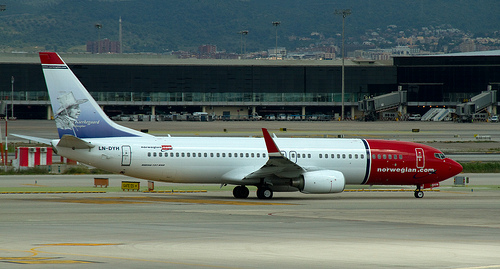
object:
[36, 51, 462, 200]
plane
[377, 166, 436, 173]
logo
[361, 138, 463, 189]
front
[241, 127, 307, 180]
wing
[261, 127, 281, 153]
tip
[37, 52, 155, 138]
tip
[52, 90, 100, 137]
portrait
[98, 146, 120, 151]
letters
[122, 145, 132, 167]
door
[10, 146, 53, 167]
barrier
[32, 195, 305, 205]
lines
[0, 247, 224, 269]
lines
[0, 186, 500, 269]
concrete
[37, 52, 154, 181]
terminal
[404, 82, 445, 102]
gates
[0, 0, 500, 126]
background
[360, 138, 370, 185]
stripe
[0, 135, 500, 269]
sections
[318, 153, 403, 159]
windows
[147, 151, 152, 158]
window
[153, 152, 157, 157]
window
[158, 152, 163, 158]
window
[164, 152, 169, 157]
window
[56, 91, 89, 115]
hat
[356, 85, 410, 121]
jetway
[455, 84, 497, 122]
jetway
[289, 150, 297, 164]
door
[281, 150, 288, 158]
door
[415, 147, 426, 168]
door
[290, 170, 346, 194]
engine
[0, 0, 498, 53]
hill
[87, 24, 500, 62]
city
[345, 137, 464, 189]
side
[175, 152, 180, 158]
window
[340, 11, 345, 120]
pole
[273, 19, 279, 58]
pole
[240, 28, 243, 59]
pole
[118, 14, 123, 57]
pole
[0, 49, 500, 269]
airpot